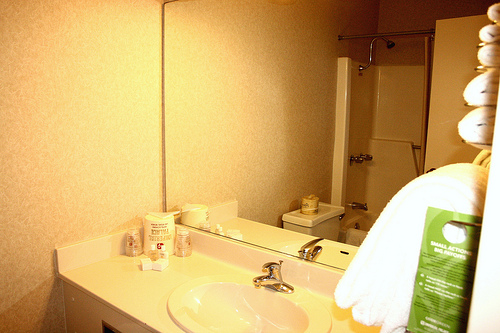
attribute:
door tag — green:
[408, 202, 487, 331]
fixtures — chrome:
[250, 260, 296, 295]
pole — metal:
[335, 29, 432, 42]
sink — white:
[165, 276, 332, 331]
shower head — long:
[344, 29, 406, 76]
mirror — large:
[162, 0, 499, 279]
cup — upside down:
[119, 225, 149, 260]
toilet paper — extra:
[301, 193, 318, 214]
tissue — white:
[295, 185, 323, 218]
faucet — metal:
[251, 253, 302, 303]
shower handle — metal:
[345, 152, 365, 169]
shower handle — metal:
[353, 147, 374, 164]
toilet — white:
[277, 188, 345, 232]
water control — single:
[260, 258, 284, 279]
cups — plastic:
[150, 213, 200, 255]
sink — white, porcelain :
[164, 271, 339, 331]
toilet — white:
[281, 202, 347, 233]